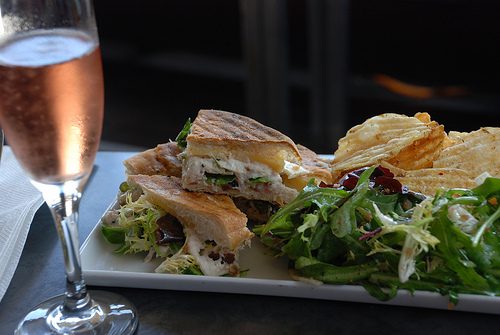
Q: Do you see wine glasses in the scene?
A: Yes, there is a wine glass.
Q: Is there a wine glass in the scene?
A: Yes, there is a wine glass.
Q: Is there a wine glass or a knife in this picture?
A: Yes, there is a wine glass.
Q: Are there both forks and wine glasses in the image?
A: No, there is a wine glass but no forks.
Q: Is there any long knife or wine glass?
A: Yes, there is a long wine glass.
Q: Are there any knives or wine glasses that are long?
A: Yes, the wine glass is long.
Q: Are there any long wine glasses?
A: Yes, there is a long wine glass.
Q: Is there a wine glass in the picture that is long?
A: Yes, there is a wine glass that is long.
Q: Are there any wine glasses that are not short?
A: Yes, there is a long wine glass.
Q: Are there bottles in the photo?
A: No, there are no bottles.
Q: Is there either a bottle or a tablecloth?
A: No, there are no bottles or tablecloths.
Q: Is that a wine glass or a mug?
A: That is a wine glass.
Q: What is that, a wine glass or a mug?
A: That is a wine glass.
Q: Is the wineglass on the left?
A: Yes, the wineglass is on the left of the image.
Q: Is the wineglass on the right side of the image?
A: No, the wineglass is on the left of the image.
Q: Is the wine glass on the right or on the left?
A: The wine glass is on the left of the image.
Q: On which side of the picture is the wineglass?
A: The wineglass is on the left of the image.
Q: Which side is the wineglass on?
A: The wineglass is on the left of the image.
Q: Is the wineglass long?
A: Yes, the wineglass is long.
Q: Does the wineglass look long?
A: Yes, the wineglass is long.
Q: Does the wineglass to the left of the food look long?
A: Yes, the wine glass is long.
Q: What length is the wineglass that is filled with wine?
A: The wineglass is long.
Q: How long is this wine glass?
A: The wine glass is long.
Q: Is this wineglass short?
A: No, the wineglass is long.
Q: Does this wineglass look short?
A: No, the wineglass is long.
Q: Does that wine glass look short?
A: No, the wine glass is long.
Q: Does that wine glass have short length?
A: No, the wine glass is long.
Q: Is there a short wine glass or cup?
A: No, there is a wine glass but it is long.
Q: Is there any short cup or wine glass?
A: No, there is a wine glass but it is long.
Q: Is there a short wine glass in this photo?
A: No, there is a wine glass but it is long.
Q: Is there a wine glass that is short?
A: No, there is a wine glass but it is long.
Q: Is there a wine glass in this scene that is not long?
A: No, there is a wine glass but it is long.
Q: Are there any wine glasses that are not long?
A: No, there is a wine glass but it is long.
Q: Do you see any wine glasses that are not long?
A: No, there is a wine glass but it is long.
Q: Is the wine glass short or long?
A: The wine glass is long.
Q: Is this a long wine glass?
A: Yes, this is a long wine glass.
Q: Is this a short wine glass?
A: No, this is a long wine glass.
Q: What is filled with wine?
A: The wine glass is filled with wine.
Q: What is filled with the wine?
A: The wine glass is filled with wine.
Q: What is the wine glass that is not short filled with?
A: The wine glass is filled with wine.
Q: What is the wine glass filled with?
A: The wine glass is filled with wine.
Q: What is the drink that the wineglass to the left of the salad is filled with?
A: The drink is wine.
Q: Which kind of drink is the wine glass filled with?
A: The wine glass is filled with wine.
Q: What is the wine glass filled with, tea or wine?
A: The wine glass is filled with wine.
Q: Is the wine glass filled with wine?
A: Yes, the wine glass is filled with wine.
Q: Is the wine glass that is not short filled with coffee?
A: No, the wine glass is filled with wine.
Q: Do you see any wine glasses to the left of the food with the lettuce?
A: Yes, there is a wine glass to the left of the food.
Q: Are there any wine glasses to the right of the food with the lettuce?
A: No, the wine glass is to the left of the food.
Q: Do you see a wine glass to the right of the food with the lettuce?
A: No, the wine glass is to the left of the food.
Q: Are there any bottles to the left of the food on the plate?
A: No, there is a wine glass to the left of the food.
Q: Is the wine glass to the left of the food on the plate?
A: Yes, the wine glass is to the left of the food.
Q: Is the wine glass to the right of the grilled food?
A: No, the wine glass is to the left of the food.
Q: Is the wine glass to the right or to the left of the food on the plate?
A: The wine glass is to the left of the food.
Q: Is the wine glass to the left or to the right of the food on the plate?
A: The wine glass is to the left of the food.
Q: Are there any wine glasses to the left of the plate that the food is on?
A: Yes, there is a wine glass to the left of the plate.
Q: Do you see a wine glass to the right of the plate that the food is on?
A: No, the wine glass is to the left of the plate.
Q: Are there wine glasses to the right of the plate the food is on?
A: No, the wine glass is to the left of the plate.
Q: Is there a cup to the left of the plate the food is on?
A: No, there is a wine glass to the left of the plate.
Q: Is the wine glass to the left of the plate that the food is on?
A: Yes, the wine glass is to the left of the plate.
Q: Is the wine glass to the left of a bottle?
A: No, the wine glass is to the left of the plate.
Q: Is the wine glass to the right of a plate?
A: No, the wine glass is to the left of a plate.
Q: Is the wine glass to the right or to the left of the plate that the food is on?
A: The wine glass is to the left of the plate.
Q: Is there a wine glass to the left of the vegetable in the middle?
A: Yes, there is a wine glass to the left of the lettuce.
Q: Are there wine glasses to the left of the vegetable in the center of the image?
A: Yes, there is a wine glass to the left of the lettuce.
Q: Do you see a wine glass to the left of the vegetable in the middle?
A: Yes, there is a wine glass to the left of the lettuce.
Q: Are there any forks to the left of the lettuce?
A: No, there is a wine glass to the left of the lettuce.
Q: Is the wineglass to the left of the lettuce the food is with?
A: Yes, the wineglass is to the left of the lettuce.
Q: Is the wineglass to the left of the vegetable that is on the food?
A: Yes, the wineglass is to the left of the lettuce.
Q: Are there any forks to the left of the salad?
A: No, there is a wine glass to the left of the salad.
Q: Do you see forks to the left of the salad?
A: No, there is a wine glass to the left of the salad.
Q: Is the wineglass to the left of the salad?
A: Yes, the wineglass is to the left of the salad.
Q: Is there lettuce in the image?
A: Yes, there is lettuce.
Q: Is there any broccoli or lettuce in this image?
A: Yes, there is lettuce.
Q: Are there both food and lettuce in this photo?
A: Yes, there are both lettuce and food.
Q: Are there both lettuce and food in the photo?
A: Yes, there are both lettuce and food.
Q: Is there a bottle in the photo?
A: No, there are no bottles.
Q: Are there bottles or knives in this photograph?
A: No, there are no bottles or knives.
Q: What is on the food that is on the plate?
A: The lettuce is on the food.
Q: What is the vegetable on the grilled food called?
A: The vegetable is lettuce.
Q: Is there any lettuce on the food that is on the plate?
A: Yes, there is lettuce on the food.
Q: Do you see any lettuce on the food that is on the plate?
A: Yes, there is lettuce on the food.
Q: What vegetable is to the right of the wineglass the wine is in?
A: The vegetable is lettuce.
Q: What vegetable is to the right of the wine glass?
A: The vegetable is lettuce.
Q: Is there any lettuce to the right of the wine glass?
A: Yes, there is lettuce to the right of the wine glass.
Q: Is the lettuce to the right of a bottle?
A: No, the lettuce is to the right of a wine glass.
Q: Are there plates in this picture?
A: Yes, there is a plate.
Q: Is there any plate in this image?
A: Yes, there is a plate.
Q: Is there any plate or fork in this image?
A: Yes, there is a plate.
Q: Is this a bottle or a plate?
A: This is a plate.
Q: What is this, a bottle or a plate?
A: This is a plate.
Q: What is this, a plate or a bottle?
A: This is a plate.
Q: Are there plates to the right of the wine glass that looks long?
A: Yes, there is a plate to the right of the wine glass.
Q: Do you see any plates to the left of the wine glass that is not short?
A: No, the plate is to the right of the wine glass.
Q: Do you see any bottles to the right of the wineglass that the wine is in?
A: No, there is a plate to the right of the wine glass.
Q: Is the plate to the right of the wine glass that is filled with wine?
A: Yes, the plate is to the right of the wine glass.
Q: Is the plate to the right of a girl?
A: No, the plate is to the right of the wine glass.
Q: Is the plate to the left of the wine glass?
A: No, the plate is to the right of the wine glass.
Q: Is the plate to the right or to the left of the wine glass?
A: The plate is to the right of the wine glass.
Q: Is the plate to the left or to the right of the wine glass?
A: The plate is to the right of the wine glass.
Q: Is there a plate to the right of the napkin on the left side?
A: Yes, there is a plate to the right of the napkin.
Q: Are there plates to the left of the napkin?
A: No, the plate is to the right of the napkin.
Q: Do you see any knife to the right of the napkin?
A: No, there is a plate to the right of the napkin.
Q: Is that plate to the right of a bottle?
A: No, the plate is to the right of the napkin.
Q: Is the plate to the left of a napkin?
A: No, the plate is to the right of a napkin.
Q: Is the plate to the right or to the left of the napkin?
A: The plate is to the right of the napkin.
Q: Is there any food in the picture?
A: Yes, there is food.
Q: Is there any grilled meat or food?
A: Yes, there is grilled food.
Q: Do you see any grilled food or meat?
A: Yes, there is grilled food.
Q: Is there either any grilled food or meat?
A: Yes, there is grilled food.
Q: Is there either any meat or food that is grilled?
A: Yes, the food is grilled.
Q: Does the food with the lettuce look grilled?
A: Yes, the food is grilled.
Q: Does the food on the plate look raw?
A: No, the food is grilled.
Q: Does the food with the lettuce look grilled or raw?
A: The food is grilled.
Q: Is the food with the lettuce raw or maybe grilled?
A: The food is grilled.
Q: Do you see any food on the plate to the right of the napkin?
A: Yes, there is food on the plate.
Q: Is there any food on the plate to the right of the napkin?
A: Yes, there is food on the plate.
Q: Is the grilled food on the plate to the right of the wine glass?
A: Yes, the food is on the plate.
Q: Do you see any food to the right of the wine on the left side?
A: Yes, there is food to the right of the wine.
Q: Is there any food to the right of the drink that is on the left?
A: Yes, there is food to the right of the wine.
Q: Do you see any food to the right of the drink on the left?
A: Yes, there is food to the right of the wine.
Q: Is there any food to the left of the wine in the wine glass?
A: No, the food is to the right of the wine.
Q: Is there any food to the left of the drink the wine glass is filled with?
A: No, the food is to the right of the wine.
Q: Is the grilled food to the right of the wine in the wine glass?
A: Yes, the food is to the right of the wine.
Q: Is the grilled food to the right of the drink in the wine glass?
A: Yes, the food is to the right of the wine.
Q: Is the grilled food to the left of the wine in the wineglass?
A: No, the food is to the right of the wine.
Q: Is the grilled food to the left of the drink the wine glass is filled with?
A: No, the food is to the right of the wine.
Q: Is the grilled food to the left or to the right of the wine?
A: The food is to the right of the wine.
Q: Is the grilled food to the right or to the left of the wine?
A: The food is to the right of the wine.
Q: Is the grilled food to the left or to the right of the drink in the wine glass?
A: The food is to the right of the wine.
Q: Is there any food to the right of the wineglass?
A: Yes, there is food to the right of the wineglass.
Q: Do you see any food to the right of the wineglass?
A: Yes, there is food to the right of the wineglass.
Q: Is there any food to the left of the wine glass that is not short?
A: No, the food is to the right of the wine glass.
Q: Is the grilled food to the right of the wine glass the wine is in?
A: Yes, the food is to the right of the wineglass.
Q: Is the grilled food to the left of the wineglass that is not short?
A: No, the food is to the right of the wine glass.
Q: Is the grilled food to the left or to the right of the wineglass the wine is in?
A: The food is to the right of the wine glass.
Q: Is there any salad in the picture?
A: Yes, there is salad.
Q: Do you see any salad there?
A: Yes, there is salad.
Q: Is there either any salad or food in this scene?
A: Yes, there is salad.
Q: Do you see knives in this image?
A: No, there are no knives.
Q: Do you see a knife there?
A: No, there are no knives.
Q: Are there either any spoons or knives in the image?
A: No, there are no knives or spoons.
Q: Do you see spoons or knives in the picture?
A: No, there are no knives or spoons.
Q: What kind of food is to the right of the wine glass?
A: The food is salad.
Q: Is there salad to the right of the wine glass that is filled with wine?
A: Yes, there is salad to the right of the wine glass.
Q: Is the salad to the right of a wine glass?
A: Yes, the salad is to the right of a wine glass.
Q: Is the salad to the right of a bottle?
A: No, the salad is to the right of a wine glass.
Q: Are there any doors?
A: Yes, there is a door.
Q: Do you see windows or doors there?
A: Yes, there is a door.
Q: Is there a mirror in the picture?
A: No, there are no mirrors.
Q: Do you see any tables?
A: Yes, there is a table.